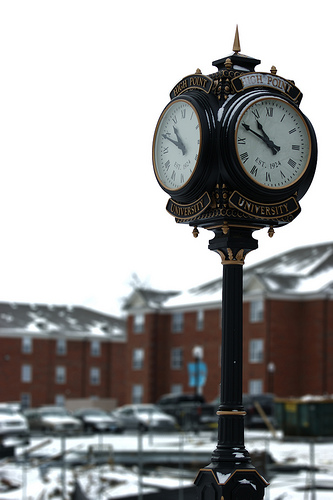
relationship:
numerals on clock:
[249, 97, 303, 140] [229, 86, 320, 191]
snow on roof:
[163, 250, 230, 344] [195, 245, 324, 322]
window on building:
[163, 300, 196, 344] [112, 315, 236, 371]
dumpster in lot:
[279, 367, 329, 426] [28, 347, 268, 499]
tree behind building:
[25, 429, 110, 498] [112, 315, 236, 371]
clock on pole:
[229, 86, 320, 191] [177, 220, 291, 450]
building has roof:
[112, 315, 236, 371] [195, 245, 324, 322]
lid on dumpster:
[287, 382, 324, 408] [279, 367, 329, 426]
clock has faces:
[229, 86, 320, 191] [239, 94, 305, 179]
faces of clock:
[239, 94, 305, 179] [229, 86, 320, 191]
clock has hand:
[229, 86, 320, 191] [233, 116, 283, 157]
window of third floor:
[163, 300, 196, 344] [159, 276, 286, 361]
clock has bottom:
[229, 86, 320, 191] [195, 202, 286, 263]